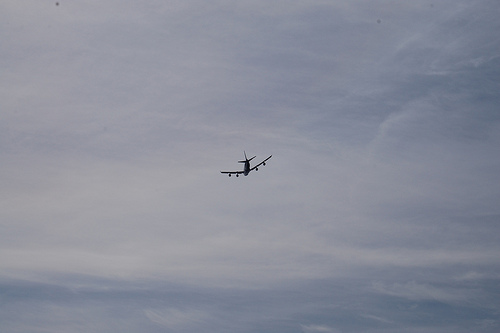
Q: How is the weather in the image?
A: It is cloudy.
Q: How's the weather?
A: It is cloudy.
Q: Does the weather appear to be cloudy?
A: Yes, it is cloudy.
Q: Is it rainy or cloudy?
A: It is cloudy.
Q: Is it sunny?
A: No, it is cloudy.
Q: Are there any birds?
A: No, there are no birds.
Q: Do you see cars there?
A: No, there are no cars.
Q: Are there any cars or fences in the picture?
A: No, there are no cars or fences.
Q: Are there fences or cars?
A: No, there are no cars or fences.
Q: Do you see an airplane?
A: Yes, there is an airplane.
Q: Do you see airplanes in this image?
A: Yes, there is an airplane.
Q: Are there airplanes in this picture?
A: Yes, there is an airplane.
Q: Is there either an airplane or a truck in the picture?
A: Yes, there is an airplane.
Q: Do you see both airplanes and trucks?
A: No, there is an airplane but no trucks.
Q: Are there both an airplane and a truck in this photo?
A: No, there is an airplane but no trucks.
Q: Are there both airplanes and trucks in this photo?
A: No, there is an airplane but no trucks.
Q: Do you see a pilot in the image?
A: No, there are no pilots.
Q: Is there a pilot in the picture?
A: No, there are no pilots.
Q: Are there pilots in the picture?
A: No, there are no pilots.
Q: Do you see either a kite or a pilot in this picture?
A: No, there are no pilots or kites.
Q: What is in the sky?
A: The plane is in the sky.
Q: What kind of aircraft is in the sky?
A: The aircraft is an airplane.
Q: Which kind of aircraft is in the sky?
A: The aircraft is an airplane.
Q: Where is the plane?
A: The plane is in the sky.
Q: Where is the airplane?
A: The plane is in the sky.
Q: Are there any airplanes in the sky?
A: Yes, there is an airplane in the sky.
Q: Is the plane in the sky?
A: Yes, the plane is in the sky.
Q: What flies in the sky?
A: The airplane flies in the sky.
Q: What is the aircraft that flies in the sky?
A: The aircraft is an airplane.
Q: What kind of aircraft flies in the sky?
A: The aircraft is an airplane.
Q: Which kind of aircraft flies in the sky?
A: The aircraft is an airplane.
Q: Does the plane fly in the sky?
A: Yes, the plane flies in the sky.